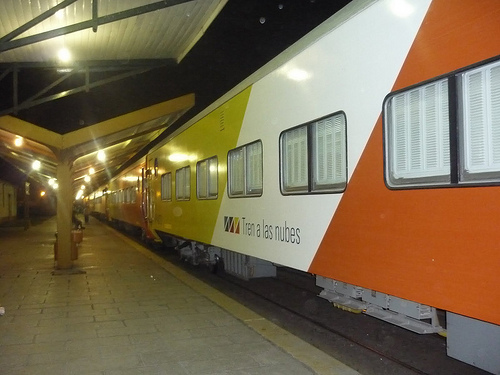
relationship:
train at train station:
[82, 1, 499, 374] [1, 0, 500, 374]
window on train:
[277, 122, 313, 198] [82, 1, 499, 374]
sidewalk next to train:
[1, 210, 358, 374] [82, 1, 499, 374]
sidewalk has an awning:
[1, 210, 358, 374] [1, 1, 231, 199]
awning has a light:
[1, 1, 231, 199] [52, 47, 75, 67]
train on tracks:
[82, 1, 499, 374] [91, 218, 497, 375]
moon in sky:
[255, 15, 269, 29] [3, 1, 352, 194]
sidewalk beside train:
[1, 210, 358, 374] [82, 1, 499, 374]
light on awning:
[96, 149, 110, 165] [1, 1, 231, 199]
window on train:
[244, 138, 265, 198] [82, 1, 499, 374]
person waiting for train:
[73, 207, 86, 233] [82, 1, 499, 374]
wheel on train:
[209, 250, 226, 276] [82, 1, 499, 374]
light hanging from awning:
[52, 47, 75, 67] [1, 1, 231, 199]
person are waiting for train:
[73, 210, 86, 229] [82, 1, 499, 374]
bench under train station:
[53, 241, 80, 263] [1, 0, 500, 374]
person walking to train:
[81, 203, 94, 225] [82, 1, 499, 374]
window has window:
[379, 72, 456, 195] [382, 75, 455, 187]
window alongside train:
[277, 122, 313, 198] [82, 1, 499, 374]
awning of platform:
[1, 1, 231, 199] [37, 268, 237, 360]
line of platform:
[91, 210, 363, 374] [43, 255, 199, 355]